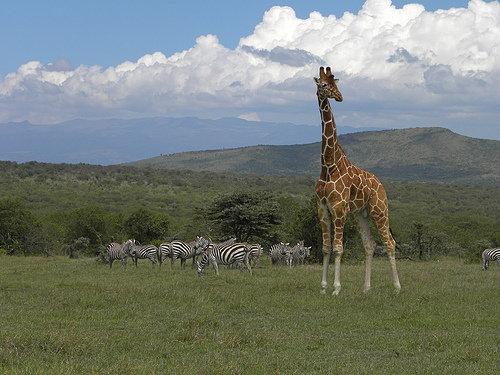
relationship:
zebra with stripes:
[100, 236, 140, 265] [198, 240, 265, 273]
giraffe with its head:
[311, 66, 403, 298] [311, 60, 353, 101]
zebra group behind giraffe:
[106, 234, 312, 275] [313, 66, 401, 294]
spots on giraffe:
[323, 168, 358, 199] [307, 60, 409, 296]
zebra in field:
[268, 240, 291, 264] [1, 249, 498, 373]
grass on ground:
[92, 291, 270, 344] [4, 256, 497, 373]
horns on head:
[317, 65, 333, 76] [311, 62, 346, 106]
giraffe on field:
[313, 66, 401, 294] [1, 249, 498, 373]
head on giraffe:
[300, 69, 344, 116] [300, 62, 400, 302]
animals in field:
[62, 62, 498, 299] [78, 284, 279, 346]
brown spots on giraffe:
[325, 175, 368, 197] [316, 76, 341, 292]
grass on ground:
[176, 327, 386, 366] [17, 277, 304, 362]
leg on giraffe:
[327, 232, 344, 278] [309, 109, 374, 216]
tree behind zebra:
[8, 207, 51, 259] [101, 240, 137, 265]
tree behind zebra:
[8, 207, 51, 259] [123, 243, 155, 265]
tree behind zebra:
[8, 207, 51, 259] [164, 235, 198, 263]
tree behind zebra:
[8, 207, 51, 259] [205, 241, 267, 273]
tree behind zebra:
[8, 207, 51, 259] [271, 239, 294, 264]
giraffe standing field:
[313, 66, 401, 294] [225, 282, 481, 336]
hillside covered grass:
[144, 130, 456, 217] [239, 257, 441, 340]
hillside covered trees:
[144, 130, 456, 217] [187, 173, 441, 255]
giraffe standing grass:
[311, 66, 403, 298] [68, 279, 453, 360]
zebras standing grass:
[62, 221, 310, 282] [93, 273, 300, 322]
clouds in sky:
[0, 0, 499, 122] [25, 18, 462, 118]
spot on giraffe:
[325, 120, 333, 136] [313, 66, 401, 294]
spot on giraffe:
[335, 156, 349, 176] [313, 66, 401, 294]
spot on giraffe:
[316, 177, 326, 198] [313, 66, 401, 294]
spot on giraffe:
[375, 182, 387, 202] [313, 66, 401, 294]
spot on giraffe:
[347, 181, 357, 204] [313, 66, 401, 294]